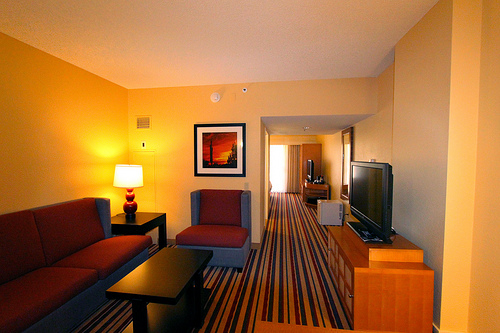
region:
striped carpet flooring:
[260, 192, 330, 331]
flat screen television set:
[341, 154, 409, 246]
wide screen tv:
[342, 158, 409, 250]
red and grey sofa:
[0, 192, 143, 326]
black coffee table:
[97, 235, 231, 319]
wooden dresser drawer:
[315, 224, 429, 327]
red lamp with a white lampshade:
[105, 158, 154, 219]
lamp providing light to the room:
[110, 156, 152, 219]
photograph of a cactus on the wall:
[185, 116, 252, 181]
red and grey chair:
[176, 181, 259, 271]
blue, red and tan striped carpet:
[70, 191, 355, 331]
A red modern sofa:
[0, 196, 152, 327]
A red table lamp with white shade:
[112, 162, 144, 213]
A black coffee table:
[105, 246, 213, 332]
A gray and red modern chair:
[175, 189, 252, 269]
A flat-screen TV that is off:
[347, 161, 392, 243]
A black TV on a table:
[302, 159, 329, 209]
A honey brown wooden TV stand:
[325, 221, 435, 331]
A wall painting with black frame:
[193, 123, 247, 176]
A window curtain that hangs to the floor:
[287, 145, 302, 192]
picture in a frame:
[183, 118, 250, 179]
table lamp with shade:
[108, 161, 147, 218]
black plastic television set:
[335, 157, 402, 247]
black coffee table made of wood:
[104, 240, 224, 332]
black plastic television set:
[299, 155, 320, 185]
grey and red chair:
[170, 178, 262, 270]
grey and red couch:
[0, 189, 149, 329]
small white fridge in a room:
[308, 193, 350, 229]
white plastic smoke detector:
[204, 86, 225, 108]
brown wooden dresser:
[322, 215, 445, 331]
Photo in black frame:
[189, 122, 248, 178]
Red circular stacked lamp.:
[113, 160, 148, 220]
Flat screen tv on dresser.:
[346, 157, 400, 246]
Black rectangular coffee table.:
[103, 243, 215, 332]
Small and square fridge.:
[313, 198, 345, 228]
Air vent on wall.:
[132, 115, 154, 130]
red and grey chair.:
[172, 185, 252, 270]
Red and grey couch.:
[0, 190, 153, 330]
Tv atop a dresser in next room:
[300, 153, 333, 210]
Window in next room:
[271, 145, 287, 195]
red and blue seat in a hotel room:
[174, 186, 254, 270]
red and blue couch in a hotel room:
[0, 195, 155, 328]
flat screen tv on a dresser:
[348, 154, 398, 246]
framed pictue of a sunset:
[195, 126, 245, 178]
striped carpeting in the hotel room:
[55, 191, 357, 331]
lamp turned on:
[115, 166, 145, 220]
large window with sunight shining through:
[266, 146, 288, 193]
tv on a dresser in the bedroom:
[304, 159, 330, 199]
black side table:
[108, 209, 165, 243]